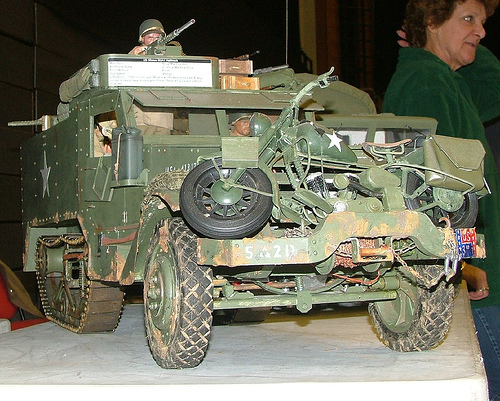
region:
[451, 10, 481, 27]
the right eye on a person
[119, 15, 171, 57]
a siolder on top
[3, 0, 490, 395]
a toy army tanker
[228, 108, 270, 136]
a man inside the tanker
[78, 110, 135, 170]
the left window on tanker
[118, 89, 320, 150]
the front windshield on tank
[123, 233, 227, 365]
the front right tire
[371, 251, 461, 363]
the left front tire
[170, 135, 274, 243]
a spare tire on hood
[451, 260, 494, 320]
the hand of person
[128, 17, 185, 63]
Man behind a gun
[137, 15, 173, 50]
Man wearing green hat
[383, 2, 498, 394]
Woman standing beside a tanker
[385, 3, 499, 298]
Woman wearing green sweater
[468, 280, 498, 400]
Woman wearing blue jeans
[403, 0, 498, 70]
Woman with curly brown hair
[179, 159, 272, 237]
Black tyre on tanker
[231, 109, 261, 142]
Man sitting inside the vehicle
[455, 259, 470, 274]
A gold colored bracelet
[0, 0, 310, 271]
Brown wall made of wood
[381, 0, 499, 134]
woman wearing a green shirt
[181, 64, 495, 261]
green toy army motorcycle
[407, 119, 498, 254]
green army motorcyle saddle bag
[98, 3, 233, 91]
toy soldier tank gunner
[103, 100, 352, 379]
toy soldier driving toy tank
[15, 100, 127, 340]
white star on side of toy tank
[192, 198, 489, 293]
front bumper of toy army tank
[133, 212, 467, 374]
front wheels of toy army tank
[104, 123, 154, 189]
army five gallon fuel can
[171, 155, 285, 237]
Front wheel of toy army motorcycle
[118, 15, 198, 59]
a man on the machine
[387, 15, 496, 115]
a woman near the machine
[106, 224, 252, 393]
wheel of the machine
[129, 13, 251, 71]
a man holding the gun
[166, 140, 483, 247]
wheel of the bike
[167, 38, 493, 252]
a bike in front of machine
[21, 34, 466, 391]
a military jeep in road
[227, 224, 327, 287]
number of the jeep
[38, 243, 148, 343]
a iron wheel of the jeep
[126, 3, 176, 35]
a man wearing cap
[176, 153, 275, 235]
one round black motorcycle wheel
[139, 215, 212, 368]
one round black mud covered wheel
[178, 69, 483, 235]
one green toy motorcycle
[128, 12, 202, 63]
one soldier figurine wearing green helmet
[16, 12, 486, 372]
one green tank figurine on display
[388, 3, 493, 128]
one woman wearing green velvet top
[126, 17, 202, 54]
one soldier statue pointing rifle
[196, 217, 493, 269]
front green bumper of tank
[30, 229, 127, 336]
metal chain tank mechanism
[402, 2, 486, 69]
one Caucasian woman with brown short hair